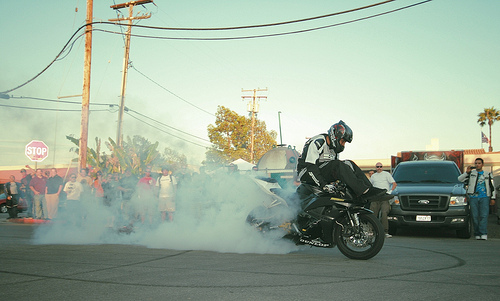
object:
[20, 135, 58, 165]
sign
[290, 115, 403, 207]
man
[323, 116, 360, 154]
helmet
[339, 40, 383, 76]
sky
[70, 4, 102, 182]
pole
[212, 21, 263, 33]
wire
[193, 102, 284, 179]
tree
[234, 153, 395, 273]
bike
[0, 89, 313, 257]
smoke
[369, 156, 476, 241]
truck